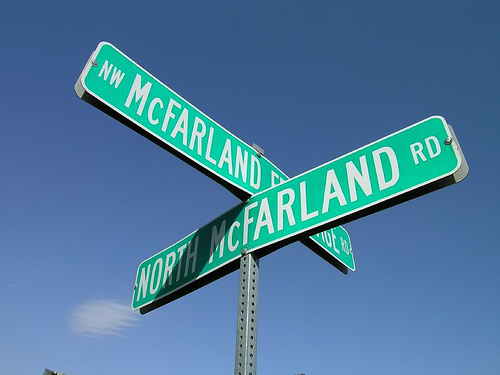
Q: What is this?
A: Street signs.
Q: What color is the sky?
A: Blue.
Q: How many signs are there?
A: 2.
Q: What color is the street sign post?
A: Gray.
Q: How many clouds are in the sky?
A: 1.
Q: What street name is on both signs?
A: Mcfarland Rd.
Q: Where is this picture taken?
A: North Mcfarland Rd.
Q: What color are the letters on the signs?
A: White.